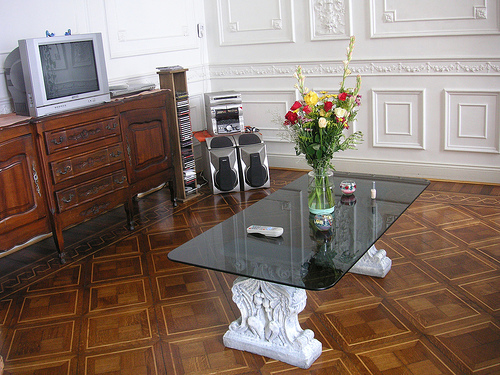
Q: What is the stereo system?
A: Silver and black.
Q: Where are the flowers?
A: Vase.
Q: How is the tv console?
A: Silver.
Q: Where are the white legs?
A: Coffee table.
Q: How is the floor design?
A: Brown squares.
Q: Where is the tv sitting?
A: A desk.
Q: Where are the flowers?
A: Vase.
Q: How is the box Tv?
A: Silver.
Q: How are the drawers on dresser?
A: Closed.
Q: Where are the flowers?
A: In a jar.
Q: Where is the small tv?
A: On cabinet.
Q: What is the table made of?
A: Glass.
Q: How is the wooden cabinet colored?
A: In brown.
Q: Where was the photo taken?
A: Living room.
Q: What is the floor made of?
A: Wood tile.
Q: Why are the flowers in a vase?
A: To support them.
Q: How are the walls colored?
A: In white.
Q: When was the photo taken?
A: Daylight.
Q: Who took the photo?
A: A photographer.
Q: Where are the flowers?
A: In a vase.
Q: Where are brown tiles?
A: On the floor.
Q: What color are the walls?
A: White.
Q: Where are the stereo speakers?
A: By the stereo.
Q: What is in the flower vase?
A: Water.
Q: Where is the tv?
A: On top of the stand.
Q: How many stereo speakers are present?
A: Two.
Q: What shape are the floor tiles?
A: Square.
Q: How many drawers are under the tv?
A: Three.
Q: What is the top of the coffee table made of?
A: Glass.